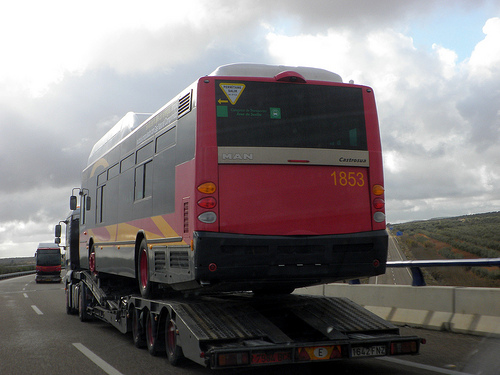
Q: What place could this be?
A: It is a highway.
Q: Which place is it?
A: It is a highway.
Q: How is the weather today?
A: It is cloudy.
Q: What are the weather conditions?
A: It is cloudy.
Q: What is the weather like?
A: It is cloudy.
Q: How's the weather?
A: It is cloudy.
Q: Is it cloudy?
A: Yes, it is cloudy.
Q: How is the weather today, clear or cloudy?
A: It is cloudy.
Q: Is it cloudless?
A: No, it is cloudy.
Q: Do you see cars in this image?
A: No, there are no cars.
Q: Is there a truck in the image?
A: Yes, there is a truck.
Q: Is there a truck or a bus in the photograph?
A: Yes, there is a truck.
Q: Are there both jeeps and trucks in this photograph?
A: No, there is a truck but no jeeps.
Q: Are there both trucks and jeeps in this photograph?
A: No, there is a truck but no jeeps.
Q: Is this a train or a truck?
A: This is a truck.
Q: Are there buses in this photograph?
A: Yes, there is a bus.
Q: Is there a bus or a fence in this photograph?
A: Yes, there is a bus.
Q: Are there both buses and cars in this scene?
A: No, there is a bus but no cars.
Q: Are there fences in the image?
A: No, there are no fences.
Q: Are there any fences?
A: No, there are no fences.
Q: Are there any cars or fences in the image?
A: No, there are no fences or cars.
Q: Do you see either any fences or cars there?
A: No, there are no fences or cars.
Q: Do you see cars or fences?
A: No, there are no fences or cars.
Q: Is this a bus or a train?
A: This is a bus.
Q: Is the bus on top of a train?
A: No, the bus is on top of the truck.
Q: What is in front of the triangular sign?
A: The bus is in front of the sign.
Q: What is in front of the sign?
A: The bus is in front of the sign.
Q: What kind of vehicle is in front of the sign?
A: The vehicle is a bus.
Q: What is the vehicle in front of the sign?
A: The vehicle is a bus.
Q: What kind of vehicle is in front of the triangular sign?
A: The vehicle is a bus.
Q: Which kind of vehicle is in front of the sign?
A: The vehicle is a bus.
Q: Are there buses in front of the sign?
A: Yes, there is a bus in front of the sign.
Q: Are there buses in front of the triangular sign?
A: Yes, there is a bus in front of the sign.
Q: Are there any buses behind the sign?
A: No, the bus is in front of the sign.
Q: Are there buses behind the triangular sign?
A: No, the bus is in front of the sign.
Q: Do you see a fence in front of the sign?
A: No, there is a bus in front of the sign.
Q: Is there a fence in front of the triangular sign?
A: No, there is a bus in front of the sign.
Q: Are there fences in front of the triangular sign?
A: No, there is a bus in front of the sign.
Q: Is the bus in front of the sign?
A: Yes, the bus is in front of the sign.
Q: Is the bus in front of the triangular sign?
A: Yes, the bus is in front of the sign.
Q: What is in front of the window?
A: The bus is in front of the window.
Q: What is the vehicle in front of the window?
A: The vehicle is a bus.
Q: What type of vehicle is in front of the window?
A: The vehicle is a bus.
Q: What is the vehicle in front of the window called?
A: The vehicle is a bus.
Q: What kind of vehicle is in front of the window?
A: The vehicle is a bus.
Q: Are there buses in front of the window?
A: Yes, there is a bus in front of the window.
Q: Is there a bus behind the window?
A: No, the bus is in front of the window.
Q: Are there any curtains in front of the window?
A: No, there is a bus in front of the window.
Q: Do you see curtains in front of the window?
A: No, there is a bus in front of the window.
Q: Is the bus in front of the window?
A: Yes, the bus is in front of the window.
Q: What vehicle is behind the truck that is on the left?
A: The vehicle is a bus.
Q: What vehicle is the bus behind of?
A: The bus is behind the truck.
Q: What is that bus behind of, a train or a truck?
A: The bus is behind a truck.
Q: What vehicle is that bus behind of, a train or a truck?
A: The bus is behind a truck.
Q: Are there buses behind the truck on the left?
A: Yes, there is a bus behind the truck.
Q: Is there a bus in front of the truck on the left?
A: No, the bus is behind the truck.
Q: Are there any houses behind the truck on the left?
A: No, there is a bus behind the truck.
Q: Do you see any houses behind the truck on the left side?
A: No, there is a bus behind the truck.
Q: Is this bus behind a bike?
A: No, the bus is behind the truck.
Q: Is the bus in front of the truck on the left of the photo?
A: No, the bus is behind the truck.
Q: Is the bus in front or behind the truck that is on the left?
A: The bus is behind the truck.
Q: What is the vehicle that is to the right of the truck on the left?
A: The vehicle is a bus.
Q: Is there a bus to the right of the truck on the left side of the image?
A: Yes, there is a bus to the right of the truck.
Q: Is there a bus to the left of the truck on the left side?
A: No, the bus is to the right of the truck.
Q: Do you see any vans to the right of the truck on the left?
A: No, there is a bus to the right of the truck.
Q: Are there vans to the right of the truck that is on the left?
A: No, there is a bus to the right of the truck.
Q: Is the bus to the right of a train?
A: No, the bus is to the right of the truck.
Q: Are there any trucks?
A: Yes, there is a truck.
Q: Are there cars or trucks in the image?
A: Yes, there is a truck.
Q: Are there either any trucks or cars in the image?
A: Yes, there is a truck.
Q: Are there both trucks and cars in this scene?
A: No, there is a truck but no cars.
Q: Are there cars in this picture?
A: No, there are no cars.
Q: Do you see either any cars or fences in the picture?
A: No, there are no cars or fences.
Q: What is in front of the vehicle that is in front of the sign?
A: The truck is in front of the bus.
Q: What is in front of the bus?
A: The truck is in front of the bus.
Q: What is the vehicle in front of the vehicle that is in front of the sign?
A: The vehicle is a truck.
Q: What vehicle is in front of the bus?
A: The vehicle is a truck.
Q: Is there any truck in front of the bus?
A: Yes, there is a truck in front of the bus.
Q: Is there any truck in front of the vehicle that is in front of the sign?
A: Yes, there is a truck in front of the bus.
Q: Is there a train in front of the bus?
A: No, there is a truck in front of the bus.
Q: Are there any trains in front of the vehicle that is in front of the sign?
A: No, there is a truck in front of the bus.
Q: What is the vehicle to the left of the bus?
A: The vehicle is a truck.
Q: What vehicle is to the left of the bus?
A: The vehicle is a truck.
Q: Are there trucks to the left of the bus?
A: Yes, there is a truck to the left of the bus.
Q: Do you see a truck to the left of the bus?
A: Yes, there is a truck to the left of the bus.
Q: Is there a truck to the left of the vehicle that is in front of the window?
A: Yes, there is a truck to the left of the bus.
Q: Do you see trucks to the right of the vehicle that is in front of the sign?
A: No, the truck is to the left of the bus.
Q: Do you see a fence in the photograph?
A: No, there are no fences.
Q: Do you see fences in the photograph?
A: No, there are no fences.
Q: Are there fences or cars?
A: No, there are no fences or cars.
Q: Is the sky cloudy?
A: Yes, the sky is cloudy.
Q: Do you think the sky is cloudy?
A: Yes, the sky is cloudy.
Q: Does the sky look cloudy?
A: Yes, the sky is cloudy.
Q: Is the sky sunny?
A: No, the sky is cloudy.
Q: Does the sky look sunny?
A: No, the sky is cloudy.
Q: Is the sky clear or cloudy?
A: The sky is cloudy.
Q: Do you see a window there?
A: Yes, there is a window.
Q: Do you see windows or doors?
A: Yes, there is a window.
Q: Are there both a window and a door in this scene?
A: No, there is a window but no doors.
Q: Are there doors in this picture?
A: No, there are no doors.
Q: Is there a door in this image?
A: No, there are no doors.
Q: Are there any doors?
A: No, there are no doors.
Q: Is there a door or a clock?
A: No, there are no doors or clocks.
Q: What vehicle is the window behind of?
A: The window is behind the bus.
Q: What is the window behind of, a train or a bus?
A: The window is behind a bus.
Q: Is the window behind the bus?
A: Yes, the window is behind the bus.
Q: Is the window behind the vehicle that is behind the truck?
A: Yes, the window is behind the bus.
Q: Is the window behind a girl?
A: No, the window is behind the bus.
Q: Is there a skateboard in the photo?
A: No, there are no skateboards.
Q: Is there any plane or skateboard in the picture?
A: No, there are no skateboards or airplanes.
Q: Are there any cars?
A: No, there are no cars.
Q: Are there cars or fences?
A: No, there are no cars or fences.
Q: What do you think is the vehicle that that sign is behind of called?
A: The vehicle is a bus.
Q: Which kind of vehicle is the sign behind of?
A: The sign is behind the bus.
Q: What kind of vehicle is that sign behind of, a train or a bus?
A: The sign is behind a bus.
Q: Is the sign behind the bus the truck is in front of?
A: Yes, the sign is behind the bus.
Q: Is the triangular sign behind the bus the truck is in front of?
A: Yes, the sign is behind the bus.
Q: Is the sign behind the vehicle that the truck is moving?
A: Yes, the sign is behind the bus.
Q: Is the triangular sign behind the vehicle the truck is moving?
A: Yes, the sign is behind the bus.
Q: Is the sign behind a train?
A: No, the sign is behind the bus.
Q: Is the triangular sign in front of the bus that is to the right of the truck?
A: No, the sign is behind the bus.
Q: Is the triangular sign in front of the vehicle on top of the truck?
A: No, the sign is behind the bus.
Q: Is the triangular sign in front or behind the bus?
A: The sign is behind the bus.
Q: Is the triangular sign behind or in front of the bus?
A: The sign is behind the bus.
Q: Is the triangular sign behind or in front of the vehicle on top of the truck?
A: The sign is behind the bus.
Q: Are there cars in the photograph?
A: No, there are no cars.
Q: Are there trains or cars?
A: No, there are no cars or trains.